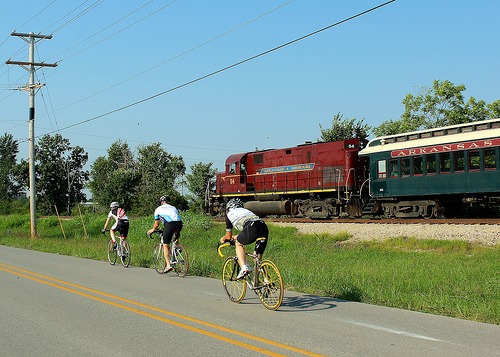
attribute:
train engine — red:
[213, 136, 365, 197]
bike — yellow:
[213, 234, 287, 312]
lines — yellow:
[0, 255, 329, 356]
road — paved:
[0, 243, 499, 355]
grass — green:
[0, 215, 498, 324]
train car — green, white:
[356, 117, 500, 194]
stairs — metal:
[358, 196, 379, 215]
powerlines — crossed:
[1, 1, 399, 154]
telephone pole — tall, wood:
[7, 26, 50, 239]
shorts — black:
[237, 219, 269, 253]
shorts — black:
[159, 219, 182, 244]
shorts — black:
[111, 217, 133, 238]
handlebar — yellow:
[211, 239, 234, 258]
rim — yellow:
[220, 256, 245, 302]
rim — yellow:
[255, 260, 283, 312]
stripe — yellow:
[211, 187, 339, 199]